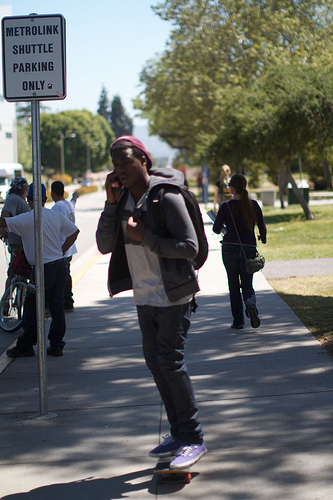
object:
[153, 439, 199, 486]
skateboard has a man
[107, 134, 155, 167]
cap is on man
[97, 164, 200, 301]
jacket is on man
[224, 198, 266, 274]
shoulder carries pur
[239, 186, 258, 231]
ponytail is on girl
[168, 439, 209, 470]
tennis shoes on boy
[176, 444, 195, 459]
laces are on shoes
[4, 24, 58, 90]
lettering is black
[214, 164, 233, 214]
woman has ponytail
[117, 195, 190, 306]
teeshirt is white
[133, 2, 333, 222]
tree is deciduous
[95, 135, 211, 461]
man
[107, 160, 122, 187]
cell phone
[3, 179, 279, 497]
sidewalk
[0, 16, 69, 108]
sign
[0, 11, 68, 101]
border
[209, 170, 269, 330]
girl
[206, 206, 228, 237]
books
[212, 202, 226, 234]
arm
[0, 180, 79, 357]
guy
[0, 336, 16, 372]
curb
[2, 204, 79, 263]
t-shirt